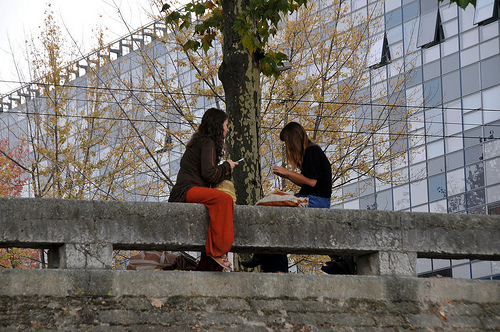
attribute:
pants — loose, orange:
[206, 188, 247, 330]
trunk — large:
[215, 36, 265, 168]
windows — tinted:
[393, 52, 477, 216]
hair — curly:
[201, 107, 230, 167]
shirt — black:
[306, 146, 338, 207]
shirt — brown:
[171, 130, 225, 198]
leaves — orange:
[3, 142, 29, 198]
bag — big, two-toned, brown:
[258, 189, 304, 214]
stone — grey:
[12, 284, 456, 320]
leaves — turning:
[197, 10, 276, 49]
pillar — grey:
[58, 235, 123, 273]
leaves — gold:
[290, 25, 362, 114]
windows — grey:
[391, 16, 491, 69]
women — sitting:
[191, 107, 349, 221]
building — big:
[25, 1, 498, 160]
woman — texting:
[183, 86, 241, 273]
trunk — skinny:
[39, 245, 50, 277]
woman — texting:
[273, 125, 333, 210]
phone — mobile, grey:
[228, 147, 256, 187]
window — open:
[369, 38, 403, 85]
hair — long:
[281, 119, 310, 170]